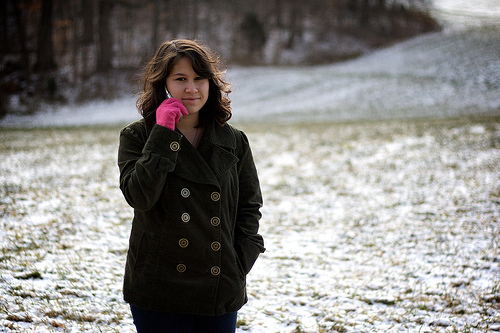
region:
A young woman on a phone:
[116, 42, 258, 330]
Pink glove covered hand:
[154, 96, 191, 131]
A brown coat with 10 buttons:
[115, 116, 265, 316]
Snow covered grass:
[313, 125, 498, 331]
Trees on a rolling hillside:
[7, 4, 449, 85]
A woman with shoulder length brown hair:
[135, 39, 236, 132]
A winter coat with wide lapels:
[120, 119, 267, 309]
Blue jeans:
[127, 302, 238, 331]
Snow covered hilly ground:
[4, 3, 498, 321]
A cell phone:
[156, 85, 187, 125]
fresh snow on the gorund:
[372, 264, 479, 326]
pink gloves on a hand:
[126, 95, 222, 142]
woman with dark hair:
[115, 37, 242, 126]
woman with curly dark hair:
[121, 33, 243, 135]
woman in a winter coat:
[63, 25, 259, 298]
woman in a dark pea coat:
[73, 36, 263, 313]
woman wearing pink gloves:
[88, 47, 248, 144]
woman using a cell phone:
[121, 36, 241, 125]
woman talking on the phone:
[148, 44, 215, 209]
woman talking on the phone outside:
[134, 30, 276, 253]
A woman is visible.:
[168, 83, 241, 326]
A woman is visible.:
[155, 65, 219, 259]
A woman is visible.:
[133, 40, 264, 322]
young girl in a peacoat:
[107, 30, 275, 331]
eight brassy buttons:
[172, 180, 222, 279]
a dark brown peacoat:
[102, 111, 274, 319]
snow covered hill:
[222, 11, 499, 136]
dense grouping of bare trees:
[2, 0, 440, 102]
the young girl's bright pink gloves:
[147, 93, 194, 135]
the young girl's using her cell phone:
[138, 77, 185, 124]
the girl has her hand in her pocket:
[213, 224, 282, 286]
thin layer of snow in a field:
[2, 130, 497, 331]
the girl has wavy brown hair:
[133, 25, 239, 134]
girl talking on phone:
[103, 13, 275, 326]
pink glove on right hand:
[153, 93, 190, 135]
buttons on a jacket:
[202, 188, 231, 287]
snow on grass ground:
[317, 231, 482, 324]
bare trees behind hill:
[18, 8, 385, 28]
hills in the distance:
[276, 14, 496, 126]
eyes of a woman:
[166, 65, 214, 86]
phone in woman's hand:
[157, 80, 179, 103]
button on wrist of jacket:
[164, 135, 186, 157]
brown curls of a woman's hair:
[207, 45, 239, 135]